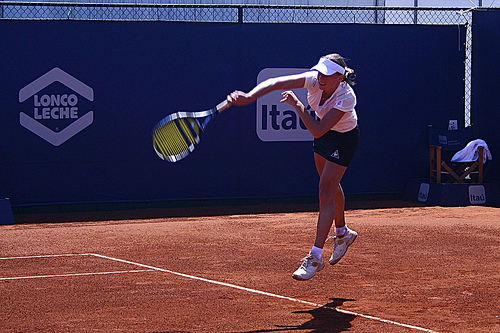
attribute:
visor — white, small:
[312, 56, 347, 77]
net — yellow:
[155, 118, 195, 155]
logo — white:
[310, 78, 317, 89]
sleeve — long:
[332, 91, 357, 116]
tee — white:
[292, 70, 363, 130]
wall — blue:
[2, 17, 498, 220]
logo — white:
[16, 65, 93, 145]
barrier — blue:
[1, 19, 498, 221]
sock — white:
[305, 242, 325, 266]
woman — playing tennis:
[147, 35, 378, 290]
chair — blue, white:
[430, 130, 478, 180]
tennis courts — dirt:
[0, 215, 498, 325]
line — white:
[0, 266, 140, 280]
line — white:
[82, 245, 432, 327]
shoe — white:
[292, 252, 328, 282]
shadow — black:
[302, 300, 352, 332]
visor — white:
[283, 38, 343, 78]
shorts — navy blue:
[316, 132, 364, 164]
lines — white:
[50, 245, 215, 277]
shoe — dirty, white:
[290, 252, 323, 283]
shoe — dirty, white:
[328, 226, 356, 266]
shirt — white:
[302, 70, 358, 133]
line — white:
[92, 247, 442, 331]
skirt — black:
[297, 122, 367, 175]